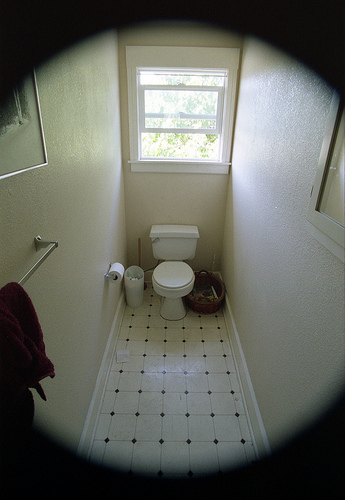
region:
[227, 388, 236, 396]
black dot on the tile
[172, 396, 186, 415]
tile is on the floor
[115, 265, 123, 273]
white tissue on the holder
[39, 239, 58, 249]
towel holder on the wall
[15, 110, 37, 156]
picture is on the wall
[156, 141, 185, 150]
window is open up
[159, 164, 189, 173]
trimming around the window is white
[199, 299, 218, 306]
straw basket on the floor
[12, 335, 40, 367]
towel hanging off the rack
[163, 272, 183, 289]
toilet lid is down on the stool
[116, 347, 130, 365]
piece of white toilet paper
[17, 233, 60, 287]
silver metal towel rack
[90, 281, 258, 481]
white tile floor with black diamond accents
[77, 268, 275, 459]
white wooden base board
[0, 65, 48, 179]
silver framed picture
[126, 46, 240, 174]
bathroom window with white edging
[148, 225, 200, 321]
white ceramic toilet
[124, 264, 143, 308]
white plastic trash can full of trash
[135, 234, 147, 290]
toilet plunger with a wooden handle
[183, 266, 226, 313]
brown wicker basket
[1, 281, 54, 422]
fluffy dark red towel on the rack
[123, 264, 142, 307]
small white garbage can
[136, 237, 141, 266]
handle of toilet plunger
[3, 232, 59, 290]
silver towel rack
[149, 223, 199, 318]
white porcelien toilet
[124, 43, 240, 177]
window with white frame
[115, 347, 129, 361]
square of toilet paper on the floor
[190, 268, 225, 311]
basket next to the toilet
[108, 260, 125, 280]
roll of toilet paper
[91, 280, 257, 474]
white tile floor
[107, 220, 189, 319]
Toilet in a bathroom.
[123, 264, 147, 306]
Trash can in a bathroom.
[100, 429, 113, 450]
Black diamonds in the tile.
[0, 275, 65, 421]
Towel in the bathroom.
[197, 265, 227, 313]
Brown basket next to toilet.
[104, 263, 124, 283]
Roll of tissue next to the toilet.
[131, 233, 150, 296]
Plunger next to the toilet.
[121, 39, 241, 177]
Window above the toilet.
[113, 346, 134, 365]
Piece of tissue on the floor.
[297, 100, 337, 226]
Corner of the medicine cabinet.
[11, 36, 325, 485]
bathroom seen through a peephole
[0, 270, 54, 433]
towel hanging from a bar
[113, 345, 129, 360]
single ply of toilet paper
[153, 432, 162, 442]
diamond design on the floor tiles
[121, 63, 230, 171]
window open to outside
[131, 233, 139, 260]
wooden handle of the toilet plunger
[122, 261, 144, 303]
white plastic garbage can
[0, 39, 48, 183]
wall hanging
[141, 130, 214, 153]
vegetation outside in the sun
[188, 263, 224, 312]
whicker basket for magazines